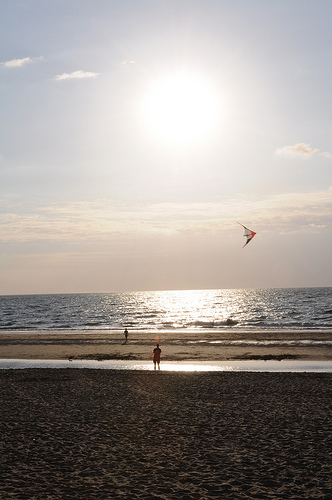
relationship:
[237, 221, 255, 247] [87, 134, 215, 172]
kite in sky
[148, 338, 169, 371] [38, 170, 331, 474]
man on beach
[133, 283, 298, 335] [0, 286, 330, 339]
sun on water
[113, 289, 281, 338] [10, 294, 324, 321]
sunset reflecting on water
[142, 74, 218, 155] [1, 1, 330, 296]
sun in sky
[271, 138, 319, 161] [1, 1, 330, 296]
cloud in sky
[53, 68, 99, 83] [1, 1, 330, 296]
cloud in sky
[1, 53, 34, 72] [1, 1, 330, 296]
cloud in sky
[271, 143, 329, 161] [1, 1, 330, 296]
cloud in sky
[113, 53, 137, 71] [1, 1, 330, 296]
cloud in sky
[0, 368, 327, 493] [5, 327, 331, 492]
sand on beach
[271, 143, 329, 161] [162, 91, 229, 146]
cloud near sun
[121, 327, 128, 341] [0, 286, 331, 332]
child walking near sea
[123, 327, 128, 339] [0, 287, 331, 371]
child walking towards water